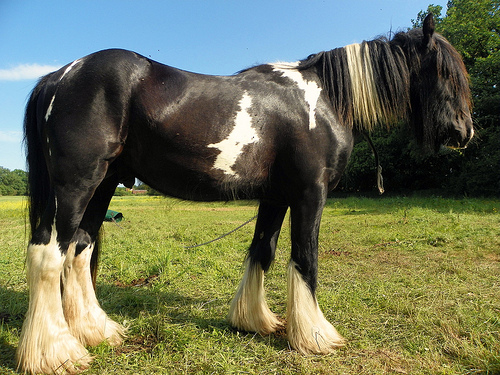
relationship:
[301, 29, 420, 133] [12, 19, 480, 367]
mane of horse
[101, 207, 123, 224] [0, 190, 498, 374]
bucket on grass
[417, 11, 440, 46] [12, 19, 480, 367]
ear of horse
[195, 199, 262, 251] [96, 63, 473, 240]
tether of horse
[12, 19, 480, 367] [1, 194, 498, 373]
horse in field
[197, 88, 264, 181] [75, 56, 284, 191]
white patch on black coat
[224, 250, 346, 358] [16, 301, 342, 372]
long hair on feet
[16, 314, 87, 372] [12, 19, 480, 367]
feet of a horse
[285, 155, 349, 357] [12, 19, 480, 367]
leg of a horse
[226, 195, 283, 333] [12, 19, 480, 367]
leg of a horse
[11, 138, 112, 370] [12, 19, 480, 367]
leg of a horse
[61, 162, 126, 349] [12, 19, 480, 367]
leg of a horse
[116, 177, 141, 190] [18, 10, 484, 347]
house in background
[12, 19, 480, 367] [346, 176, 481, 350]
horse in field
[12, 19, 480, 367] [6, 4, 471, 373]
horse standing outside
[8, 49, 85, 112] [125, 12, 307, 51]
cloud in sky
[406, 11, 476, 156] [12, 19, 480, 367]
head of a horse